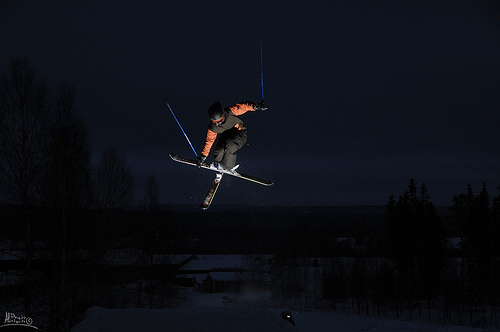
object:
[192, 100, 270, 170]
skier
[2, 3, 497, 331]
air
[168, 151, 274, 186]
ski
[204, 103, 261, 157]
jacket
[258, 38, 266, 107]
pole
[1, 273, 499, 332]
groiund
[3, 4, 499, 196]
sky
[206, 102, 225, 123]
helmet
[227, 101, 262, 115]
arm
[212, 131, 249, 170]
pants